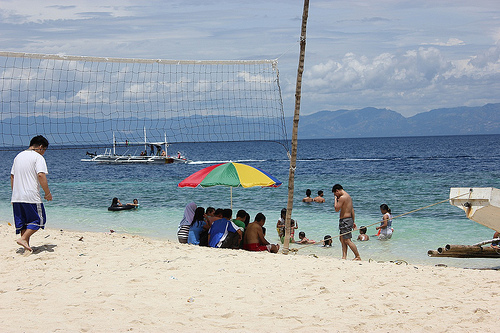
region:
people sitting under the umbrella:
[132, 109, 372, 326]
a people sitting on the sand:
[114, 57, 339, 331]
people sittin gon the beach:
[158, 116, 340, 328]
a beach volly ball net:
[4, 13, 410, 271]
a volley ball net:
[4, 15, 494, 300]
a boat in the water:
[35, 75, 393, 224]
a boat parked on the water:
[43, 52, 376, 291]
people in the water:
[286, 132, 449, 256]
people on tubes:
[99, 152, 167, 206]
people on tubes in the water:
[69, 164, 192, 234]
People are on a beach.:
[156, 128, 443, 263]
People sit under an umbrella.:
[165, 155, 298, 262]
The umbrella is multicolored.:
[165, 154, 291, 198]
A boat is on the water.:
[70, 115, 206, 170]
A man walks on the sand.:
[1, 128, 65, 265]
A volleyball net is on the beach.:
[0, 40, 319, 267]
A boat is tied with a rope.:
[277, 180, 482, 260]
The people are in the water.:
[295, 175, 335, 210]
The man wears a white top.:
[2, 143, 58, 212]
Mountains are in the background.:
[0, 91, 497, 155]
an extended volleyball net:
[5, 41, 293, 162]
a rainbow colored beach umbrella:
[174, 160, 290, 203]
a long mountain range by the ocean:
[28, 115, 498, 135]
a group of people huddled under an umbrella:
[169, 193, 275, 250]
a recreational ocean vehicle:
[78, 117, 203, 177]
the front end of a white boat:
[431, 173, 497, 208]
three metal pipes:
[422, 238, 481, 276]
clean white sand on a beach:
[144, 248, 279, 332]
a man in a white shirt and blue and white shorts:
[3, 118, 55, 257]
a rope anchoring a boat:
[360, 206, 486, 234]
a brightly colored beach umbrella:
[169, 146, 283, 203]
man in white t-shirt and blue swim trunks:
[2, 128, 62, 255]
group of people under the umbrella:
[169, 150, 286, 266]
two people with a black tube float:
[102, 190, 147, 217]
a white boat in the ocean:
[77, 121, 193, 172]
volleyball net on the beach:
[0, 38, 305, 276]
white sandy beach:
[7, 221, 499, 330]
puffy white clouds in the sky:
[4, 10, 492, 115]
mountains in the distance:
[5, 106, 499, 142]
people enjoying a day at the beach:
[6, 132, 493, 285]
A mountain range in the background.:
[3, 102, 496, 134]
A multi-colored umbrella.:
[171, 156, 285, 205]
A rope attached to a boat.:
[281, 184, 472, 252]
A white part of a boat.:
[437, 174, 498, 242]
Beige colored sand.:
[1, 218, 498, 330]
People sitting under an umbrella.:
[171, 154, 283, 262]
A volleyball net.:
[0, 50, 292, 166]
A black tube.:
[109, 203, 140, 212]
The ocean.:
[6, 130, 498, 264]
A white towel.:
[178, 200, 199, 227]